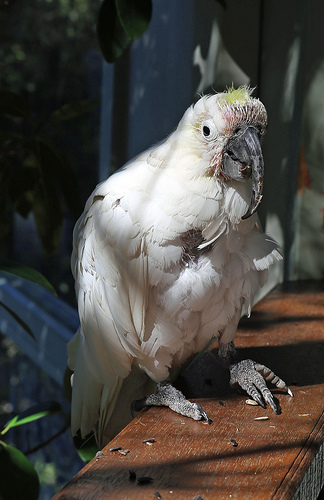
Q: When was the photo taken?
A: Daytime.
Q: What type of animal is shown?
A: Bird.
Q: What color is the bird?
A: White.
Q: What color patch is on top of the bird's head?
A: Yellow.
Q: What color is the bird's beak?
A: Gray.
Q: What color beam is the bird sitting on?
A: Brown.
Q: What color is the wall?
A: Gray.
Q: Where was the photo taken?
A: On a ledge.